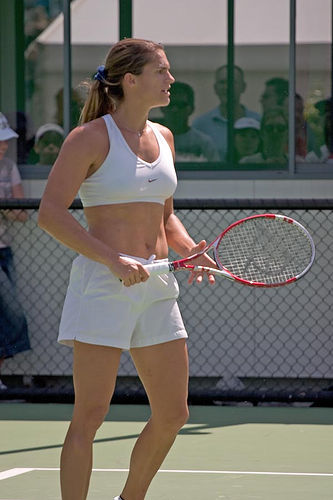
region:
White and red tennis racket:
[126, 212, 329, 353]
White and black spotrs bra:
[77, 129, 203, 226]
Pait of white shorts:
[40, 227, 227, 348]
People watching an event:
[229, 103, 260, 174]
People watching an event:
[258, 103, 311, 173]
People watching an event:
[258, 69, 287, 117]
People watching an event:
[187, 52, 242, 101]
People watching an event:
[163, 84, 199, 137]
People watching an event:
[33, 105, 72, 183]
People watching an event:
[0, 86, 59, 203]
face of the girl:
[109, 40, 194, 103]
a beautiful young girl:
[50, 55, 255, 490]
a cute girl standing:
[62, 24, 261, 487]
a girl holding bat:
[37, 185, 330, 319]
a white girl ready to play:
[48, 17, 328, 444]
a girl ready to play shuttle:
[52, 23, 326, 493]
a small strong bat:
[154, 206, 321, 300]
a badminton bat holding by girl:
[64, 211, 327, 319]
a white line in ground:
[186, 458, 330, 480]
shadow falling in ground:
[187, 397, 329, 436]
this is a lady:
[76, 68, 199, 340]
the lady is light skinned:
[142, 352, 193, 417]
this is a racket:
[184, 238, 272, 284]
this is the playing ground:
[228, 414, 302, 487]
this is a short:
[130, 294, 183, 322]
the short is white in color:
[143, 298, 172, 328]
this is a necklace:
[126, 121, 153, 136]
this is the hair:
[109, 46, 129, 68]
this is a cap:
[234, 115, 261, 126]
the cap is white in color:
[241, 119, 257, 125]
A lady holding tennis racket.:
[121, 232, 323, 303]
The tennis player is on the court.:
[47, 26, 208, 433]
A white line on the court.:
[182, 459, 306, 498]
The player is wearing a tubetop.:
[71, 125, 178, 213]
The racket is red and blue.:
[200, 217, 330, 289]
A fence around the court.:
[27, 209, 299, 375]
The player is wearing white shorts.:
[76, 245, 198, 341]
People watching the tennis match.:
[202, 65, 305, 162]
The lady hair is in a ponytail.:
[64, 44, 119, 120]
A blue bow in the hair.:
[93, 60, 104, 78]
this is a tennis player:
[33, 26, 193, 497]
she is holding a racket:
[81, 209, 314, 308]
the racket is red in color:
[198, 202, 297, 294]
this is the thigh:
[147, 347, 190, 407]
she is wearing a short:
[73, 284, 169, 333]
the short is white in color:
[82, 296, 155, 335]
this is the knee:
[154, 395, 194, 435]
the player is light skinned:
[153, 352, 177, 370]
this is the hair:
[107, 42, 140, 75]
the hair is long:
[81, 90, 106, 119]